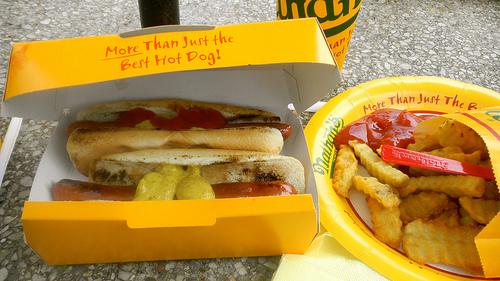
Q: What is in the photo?
A: Hot dogs and french fries.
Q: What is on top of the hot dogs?
A: Ketchup and mustard.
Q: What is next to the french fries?
A: Ketchup.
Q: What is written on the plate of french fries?
A: Nathan's and More than just the B.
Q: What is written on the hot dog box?
A: More than Just the best Hot Dog.